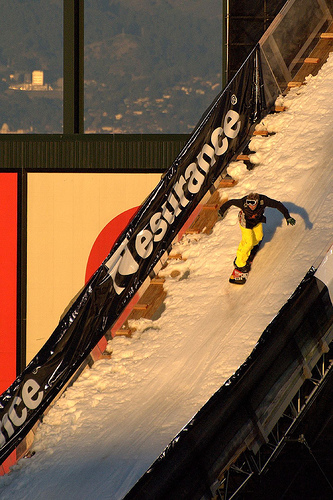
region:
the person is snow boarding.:
[209, 188, 298, 285]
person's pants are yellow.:
[230, 217, 266, 271]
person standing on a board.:
[225, 235, 265, 291]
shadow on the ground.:
[255, 199, 316, 247]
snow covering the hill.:
[2, 73, 330, 494]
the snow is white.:
[0, 103, 329, 495]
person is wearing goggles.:
[244, 195, 258, 205]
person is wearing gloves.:
[281, 215, 297, 224]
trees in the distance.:
[0, 0, 238, 140]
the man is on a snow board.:
[232, 257, 249, 285]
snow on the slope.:
[26, 124, 327, 488]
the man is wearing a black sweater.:
[220, 193, 287, 225]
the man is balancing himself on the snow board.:
[217, 191, 293, 283]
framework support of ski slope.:
[205, 342, 329, 498]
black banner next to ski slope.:
[0, 123, 246, 421]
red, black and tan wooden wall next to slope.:
[1, 134, 178, 344]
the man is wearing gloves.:
[284, 214, 296, 226]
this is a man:
[214, 178, 277, 300]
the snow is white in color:
[151, 328, 198, 371]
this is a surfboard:
[228, 268, 254, 280]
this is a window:
[89, 18, 202, 123]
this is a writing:
[127, 159, 209, 268]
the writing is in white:
[143, 210, 174, 238]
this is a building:
[31, 69, 52, 91]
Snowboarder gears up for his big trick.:
[212, 146, 315, 293]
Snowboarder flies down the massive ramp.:
[0, 119, 318, 450]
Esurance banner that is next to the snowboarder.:
[77, 71, 318, 354]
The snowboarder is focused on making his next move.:
[215, 189, 313, 286]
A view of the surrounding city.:
[2, 1, 220, 134]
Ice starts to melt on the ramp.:
[182, 33, 329, 194]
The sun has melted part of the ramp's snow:
[18, 299, 254, 440]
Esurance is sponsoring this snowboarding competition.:
[105, 94, 295, 298]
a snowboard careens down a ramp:
[215, 187, 299, 289]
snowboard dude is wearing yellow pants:
[230, 218, 262, 269]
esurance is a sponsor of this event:
[99, 87, 243, 295]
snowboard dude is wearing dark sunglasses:
[242, 195, 253, 201]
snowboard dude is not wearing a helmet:
[241, 187, 256, 206]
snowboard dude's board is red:
[224, 237, 256, 281]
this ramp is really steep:
[112, 38, 331, 369]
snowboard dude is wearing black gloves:
[282, 215, 296, 228]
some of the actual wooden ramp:
[112, 169, 234, 338]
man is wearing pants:
[237, 218, 266, 271]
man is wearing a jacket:
[215, 195, 289, 227]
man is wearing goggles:
[243, 198, 257, 207]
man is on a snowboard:
[217, 191, 293, 284]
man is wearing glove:
[285, 215, 296, 228]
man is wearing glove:
[216, 207, 224, 218]